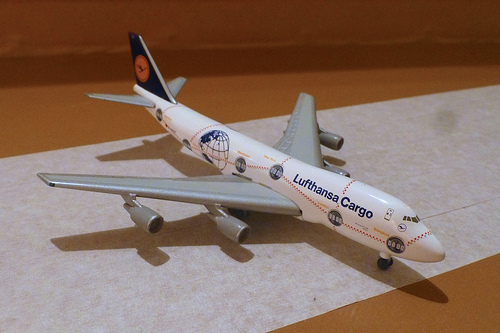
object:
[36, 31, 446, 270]
airplane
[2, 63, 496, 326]
shelf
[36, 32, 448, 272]
model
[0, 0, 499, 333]
table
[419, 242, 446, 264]
nose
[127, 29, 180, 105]
tail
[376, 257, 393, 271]
gear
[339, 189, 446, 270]
front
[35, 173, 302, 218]
wing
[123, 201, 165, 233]
engine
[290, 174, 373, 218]
lufthansa cargo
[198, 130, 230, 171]
globe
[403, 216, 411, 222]
windows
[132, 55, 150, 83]
decal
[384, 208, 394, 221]
decal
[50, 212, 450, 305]
shadow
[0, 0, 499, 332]
surface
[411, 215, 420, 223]
windshield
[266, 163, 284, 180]
logo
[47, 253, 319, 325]
paper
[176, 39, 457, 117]
reflection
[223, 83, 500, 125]
light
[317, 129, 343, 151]
booster